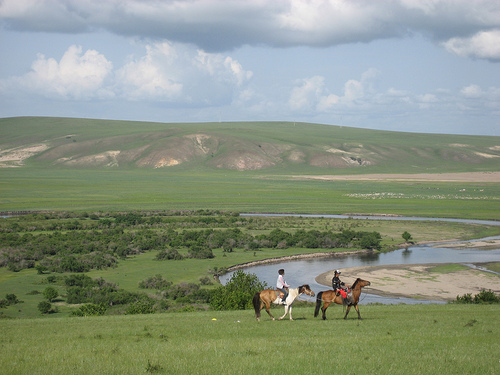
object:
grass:
[0, 302, 499, 374]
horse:
[313, 277, 372, 320]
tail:
[253, 291, 263, 318]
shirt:
[275, 273, 289, 286]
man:
[275, 269, 293, 304]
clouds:
[443, 29, 499, 62]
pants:
[334, 287, 350, 300]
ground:
[327, 263, 499, 299]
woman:
[277, 269, 289, 304]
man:
[330, 268, 351, 306]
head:
[356, 278, 371, 288]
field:
[0, 169, 499, 222]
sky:
[0, 0, 499, 137]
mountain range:
[0, 117, 499, 171]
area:
[0, 158, 499, 220]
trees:
[43, 287, 59, 303]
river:
[217, 248, 499, 305]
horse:
[251, 283, 316, 321]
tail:
[313, 291, 323, 317]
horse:
[307, 277, 371, 321]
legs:
[352, 305, 361, 317]